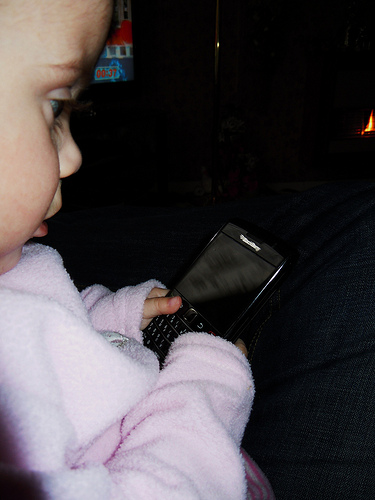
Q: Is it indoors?
A: Yes, it is indoors.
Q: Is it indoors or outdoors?
A: It is indoors.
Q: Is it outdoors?
A: No, it is indoors.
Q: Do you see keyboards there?
A: Yes, there is a keyboard.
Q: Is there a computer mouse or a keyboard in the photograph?
A: Yes, there is a keyboard.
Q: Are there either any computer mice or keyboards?
A: Yes, there is a keyboard.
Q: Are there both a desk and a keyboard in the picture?
A: No, there is a keyboard but no desks.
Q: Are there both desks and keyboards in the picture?
A: No, there is a keyboard but no desks.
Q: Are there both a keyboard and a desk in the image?
A: No, there is a keyboard but no desks.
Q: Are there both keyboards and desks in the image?
A: No, there is a keyboard but no desks.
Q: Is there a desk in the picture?
A: No, there are no desks.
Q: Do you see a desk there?
A: No, there are no desks.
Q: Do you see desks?
A: No, there are no desks.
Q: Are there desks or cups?
A: No, there are no desks or cups.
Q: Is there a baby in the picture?
A: Yes, there is a baby.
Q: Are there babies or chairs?
A: Yes, there is a baby.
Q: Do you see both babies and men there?
A: No, there is a baby but no men.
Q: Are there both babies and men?
A: No, there is a baby but no men.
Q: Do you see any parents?
A: No, there are no parents.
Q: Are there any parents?
A: No, there are no parents.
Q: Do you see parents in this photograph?
A: No, there are no parents.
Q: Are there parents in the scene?
A: No, there are no parents.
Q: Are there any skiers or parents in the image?
A: No, there are no parents or skiers.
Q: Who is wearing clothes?
A: The baby is wearing clothes.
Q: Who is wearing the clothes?
A: The baby is wearing clothes.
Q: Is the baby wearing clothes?
A: Yes, the baby is wearing clothes.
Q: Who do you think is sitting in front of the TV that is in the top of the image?
A: The baby is sitting in front of the television.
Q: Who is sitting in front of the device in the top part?
A: The baby is sitting in front of the television.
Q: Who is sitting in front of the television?
A: The baby is sitting in front of the television.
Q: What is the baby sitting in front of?
A: The baby is sitting in front of the TV.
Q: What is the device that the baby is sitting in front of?
A: The device is a television.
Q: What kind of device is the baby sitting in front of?
A: The baby is sitting in front of the television.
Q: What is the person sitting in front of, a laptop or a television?
A: The baby is sitting in front of a television.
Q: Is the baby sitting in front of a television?
A: Yes, the baby is sitting in front of a television.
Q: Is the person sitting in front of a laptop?
A: No, the baby is sitting in front of a television.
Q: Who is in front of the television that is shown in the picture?
A: The baby is in front of the television.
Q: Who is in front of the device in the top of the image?
A: The baby is in front of the television.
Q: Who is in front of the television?
A: The baby is in front of the television.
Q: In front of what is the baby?
A: The baby is in front of the TV.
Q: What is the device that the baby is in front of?
A: The device is a television.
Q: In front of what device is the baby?
A: The baby is in front of the television.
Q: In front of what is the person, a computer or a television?
A: The baby is in front of a television.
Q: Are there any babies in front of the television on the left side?
A: Yes, there is a baby in front of the television.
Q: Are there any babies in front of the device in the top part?
A: Yes, there is a baby in front of the television.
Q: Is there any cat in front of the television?
A: No, there is a baby in front of the television.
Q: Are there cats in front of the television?
A: No, there is a baby in front of the television.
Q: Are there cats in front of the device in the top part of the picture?
A: No, there is a baby in front of the television.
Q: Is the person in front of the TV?
A: Yes, the baby is in front of the TV.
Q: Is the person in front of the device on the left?
A: Yes, the baby is in front of the TV.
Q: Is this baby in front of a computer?
A: No, the baby is in front of the TV.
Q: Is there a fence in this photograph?
A: No, there are no fences.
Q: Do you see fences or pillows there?
A: No, there are no fences or pillows.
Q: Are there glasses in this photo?
A: No, there are no glasses.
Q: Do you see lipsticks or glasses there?
A: No, there are no glasses or lipsticks.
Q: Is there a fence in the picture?
A: No, there are no fences.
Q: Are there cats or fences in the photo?
A: No, there are no fences or cats.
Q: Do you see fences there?
A: No, there are no fences.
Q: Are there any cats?
A: No, there are no cats.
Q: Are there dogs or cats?
A: No, there are no cats or dogs.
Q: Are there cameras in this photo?
A: No, there are no cameras.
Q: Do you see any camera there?
A: No, there are no cameras.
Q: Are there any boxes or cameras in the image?
A: No, there are no cameras or boxes.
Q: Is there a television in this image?
A: Yes, there is a television.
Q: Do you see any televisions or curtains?
A: Yes, there is a television.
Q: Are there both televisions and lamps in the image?
A: No, there is a television but no lamps.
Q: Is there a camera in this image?
A: No, there are no cameras.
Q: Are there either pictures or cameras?
A: No, there are no cameras or pictures.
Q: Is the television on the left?
A: Yes, the television is on the left of the image.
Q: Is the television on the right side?
A: No, the television is on the left of the image.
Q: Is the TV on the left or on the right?
A: The TV is on the left of the image.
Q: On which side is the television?
A: The television is on the left of the image.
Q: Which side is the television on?
A: The television is on the left of the image.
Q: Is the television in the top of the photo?
A: Yes, the television is in the top of the image.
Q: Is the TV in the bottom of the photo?
A: No, the TV is in the top of the image.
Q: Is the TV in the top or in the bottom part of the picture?
A: The TV is in the top of the image.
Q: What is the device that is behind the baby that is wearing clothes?
A: The device is a television.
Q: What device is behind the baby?
A: The device is a television.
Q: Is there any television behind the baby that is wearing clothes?
A: Yes, there is a television behind the baby.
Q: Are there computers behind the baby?
A: No, there is a television behind the baby.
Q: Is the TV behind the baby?
A: Yes, the TV is behind the baby.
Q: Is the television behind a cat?
A: No, the television is behind the baby.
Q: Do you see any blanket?
A: No, there are no blankets.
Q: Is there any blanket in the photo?
A: No, there are no blankets.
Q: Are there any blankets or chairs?
A: No, there are no blankets or chairs.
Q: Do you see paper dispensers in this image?
A: No, there are no paper dispensers.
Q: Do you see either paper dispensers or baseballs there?
A: No, there are no paper dispensers or baseballs.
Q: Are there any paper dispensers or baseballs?
A: No, there are no paper dispensers or baseballs.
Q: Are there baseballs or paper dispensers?
A: No, there are no paper dispensers or baseballs.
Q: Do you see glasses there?
A: No, there are no glasses.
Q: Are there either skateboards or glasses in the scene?
A: No, there are no glasses or skateboards.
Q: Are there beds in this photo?
A: No, there are no beds.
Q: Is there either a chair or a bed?
A: No, there are no beds or chairs.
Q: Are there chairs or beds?
A: No, there are no beds or chairs.